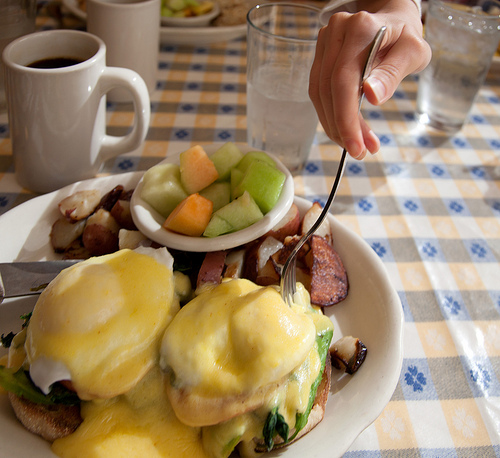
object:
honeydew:
[238, 154, 296, 214]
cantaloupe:
[175, 138, 220, 199]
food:
[301, 232, 351, 310]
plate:
[2, 167, 404, 457]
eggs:
[23, 244, 185, 404]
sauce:
[87, 343, 105, 361]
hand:
[308, 3, 432, 162]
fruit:
[137, 169, 196, 223]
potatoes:
[244, 234, 287, 289]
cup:
[0, 27, 152, 196]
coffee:
[22, 56, 91, 72]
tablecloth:
[0, 1, 499, 456]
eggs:
[155, 269, 318, 428]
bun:
[26, 354, 74, 400]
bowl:
[128, 144, 294, 255]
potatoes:
[56, 180, 109, 222]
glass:
[241, 1, 327, 176]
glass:
[410, 0, 499, 138]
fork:
[276, 23, 391, 310]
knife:
[0, 256, 90, 303]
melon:
[226, 146, 289, 214]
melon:
[198, 213, 236, 239]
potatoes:
[192, 244, 230, 295]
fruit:
[164, 189, 216, 240]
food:
[323, 332, 370, 378]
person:
[307, 0, 435, 163]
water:
[243, 83, 321, 176]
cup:
[244, 2, 328, 176]